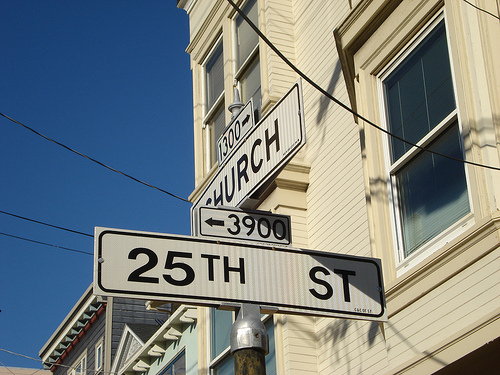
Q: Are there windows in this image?
A: Yes, there is a window.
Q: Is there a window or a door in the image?
A: Yes, there is a window.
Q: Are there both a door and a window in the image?
A: No, there is a window but no doors.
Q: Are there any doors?
A: No, there are no doors.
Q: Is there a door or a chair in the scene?
A: No, there are no doors or chairs.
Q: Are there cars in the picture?
A: No, there are no cars.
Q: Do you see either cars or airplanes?
A: No, there are no cars or airplanes.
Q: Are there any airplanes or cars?
A: No, there are no cars or airplanes.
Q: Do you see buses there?
A: No, there are no buses.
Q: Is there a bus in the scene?
A: No, there are no buses.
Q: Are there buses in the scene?
A: No, there are no buses.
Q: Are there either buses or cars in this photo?
A: No, there are no buses or cars.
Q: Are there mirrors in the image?
A: No, there are no mirrors.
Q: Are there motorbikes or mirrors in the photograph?
A: No, there are no mirrors or motorbikes.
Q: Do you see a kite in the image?
A: No, there are no kites.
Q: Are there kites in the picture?
A: No, there are no kites.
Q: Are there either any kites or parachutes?
A: No, there are no kites or parachutes.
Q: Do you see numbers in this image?
A: Yes, there are numbers.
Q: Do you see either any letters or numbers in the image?
A: Yes, there are numbers.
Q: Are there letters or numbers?
A: Yes, there are numbers.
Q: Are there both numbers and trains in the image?
A: No, there are numbers but no trains.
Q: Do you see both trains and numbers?
A: No, there are numbers but no trains.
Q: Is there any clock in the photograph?
A: No, there are no clocks.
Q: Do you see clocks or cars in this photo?
A: No, there are no clocks or cars.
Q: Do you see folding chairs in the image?
A: No, there are no folding chairs.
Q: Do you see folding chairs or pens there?
A: No, there are no folding chairs or pens.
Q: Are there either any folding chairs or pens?
A: No, there are no folding chairs or pens.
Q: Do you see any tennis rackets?
A: No, there are no tennis rackets.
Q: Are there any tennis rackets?
A: No, there are no tennis rackets.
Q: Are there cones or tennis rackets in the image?
A: No, there are no tennis rackets or cones.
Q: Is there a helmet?
A: No, there are no helmets.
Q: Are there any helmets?
A: No, there are no helmets.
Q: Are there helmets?
A: No, there are no helmets.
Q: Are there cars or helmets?
A: No, there are no helmets or cars.